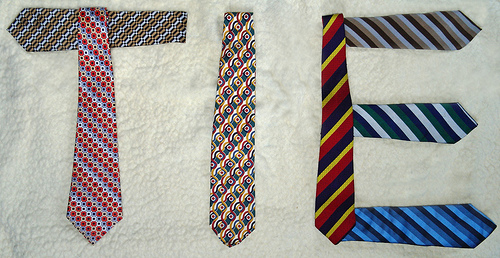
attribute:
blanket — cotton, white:
[6, 2, 495, 258]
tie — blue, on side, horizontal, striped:
[345, 194, 493, 252]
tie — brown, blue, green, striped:
[320, 2, 495, 60]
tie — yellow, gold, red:
[316, 25, 361, 244]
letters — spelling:
[15, 9, 488, 249]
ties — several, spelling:
[11, 4, 489, 252]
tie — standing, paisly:
[203, 14, 258, 247]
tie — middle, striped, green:
[324, 89, 486, 160]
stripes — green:
[379, 108, 481, 140]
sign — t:
[6, 1, 184, 258]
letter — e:
[308, 7, 499, 256]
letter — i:
[208, 5, 264, 249]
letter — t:
[11, 0, 182, 256]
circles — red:
[87, 106, 112, 122]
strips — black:
[367, 36, 408, 54]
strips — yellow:
[320, 43, 350, 74]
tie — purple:
[199, 7, 276, 253]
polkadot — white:
[80, 35, 108, 58]